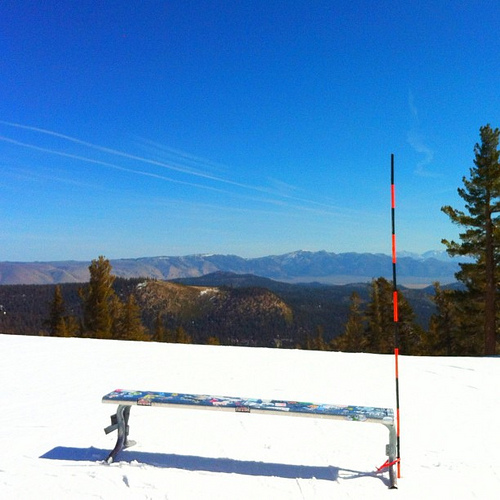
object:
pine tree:
[428, 122, 499, 357]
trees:
[302, 267, 431, 355]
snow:
[54, 337, 376, 385]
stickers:
[100, 388, 394, 426]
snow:
[407, 372, 499, 497]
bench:
[100, 387, 398, 489]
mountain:
[0, 250, 478, 355]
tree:
[45, 284, 83, 336]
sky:
[0, 0, 127, 98]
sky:
[228, 0, 499, 122]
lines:
[0, 113, 364, 223]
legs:
[106, 404, 128, 466]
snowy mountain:
[0, 334, 499, 497]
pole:
[389, 152, 401, 478]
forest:
[0, 123, 499, 356]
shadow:
[38, 445, 390, 490]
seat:
[100, 388, 394, 424]